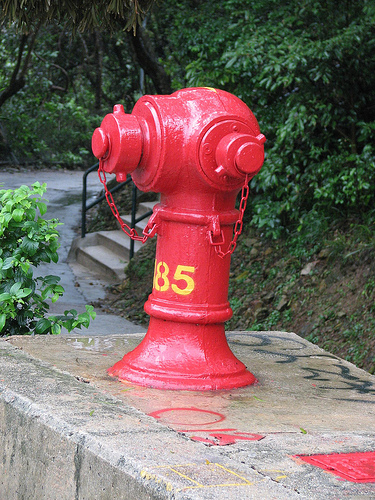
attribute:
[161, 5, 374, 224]
leaves — drooping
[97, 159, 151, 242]
chain — attached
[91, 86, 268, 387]
hydrant — red, fire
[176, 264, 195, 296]
number — written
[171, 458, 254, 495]
platform — painted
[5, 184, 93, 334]
plant — covering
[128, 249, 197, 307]
number — yellow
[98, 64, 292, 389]
hydrant — brightly colored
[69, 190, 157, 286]
stairs — cement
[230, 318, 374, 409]
graffiti — black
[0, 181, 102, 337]
shrub — green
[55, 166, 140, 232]
railing — black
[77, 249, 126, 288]
concrete stair — set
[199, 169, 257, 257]
chain — attached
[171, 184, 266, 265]
chain — bright red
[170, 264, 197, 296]
number — painted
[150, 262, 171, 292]
number — painted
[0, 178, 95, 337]
plant — green, full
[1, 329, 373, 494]
platform — concrete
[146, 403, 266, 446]
graffiti — red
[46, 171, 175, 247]
rail — black, metal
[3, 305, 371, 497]
platform — cement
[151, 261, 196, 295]
85 — painted, stenciled, yellow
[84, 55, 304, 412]
hydrant — birght, red